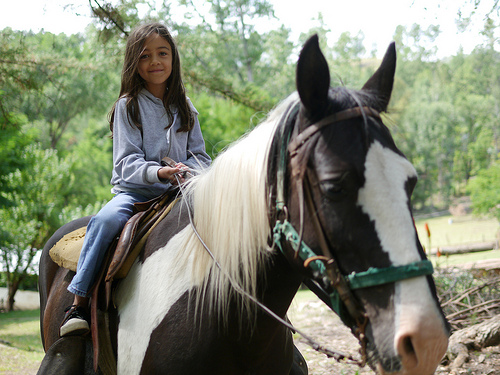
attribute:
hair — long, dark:
[109, 30, 159, 84]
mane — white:
[176, 90, 299, 338]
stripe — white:
[357, 140, 451, 355]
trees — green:
[2, 1, 499, 308]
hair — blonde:
[191, 142, 318, 314]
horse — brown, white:
[45, 106, 460, 372]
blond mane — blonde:
[183, 129, 287, 313]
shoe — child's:
[58, 286, 92, 342]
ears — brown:
[279, 31, 341, 118]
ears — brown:
[356, 32, 405, 117]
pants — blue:
[59, 184, 173, 305]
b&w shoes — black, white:
[53, 302, 95, 333]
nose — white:
[392, 323, 449, 361]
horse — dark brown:
[36, 30, 454, 372]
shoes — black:
[59, 299, 92, 339]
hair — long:
[106, 22, 192, 133]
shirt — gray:
[110, 90, 211, 200]